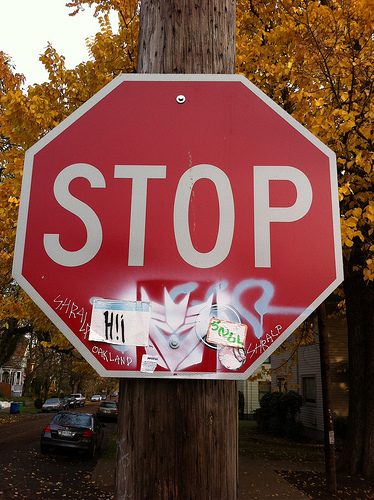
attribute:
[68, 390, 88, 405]
truck — white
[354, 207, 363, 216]
leaves — golden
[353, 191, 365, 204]
leaves — golden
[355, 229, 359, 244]
leaves — golden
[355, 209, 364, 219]
leaves — golden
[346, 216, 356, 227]
leaves — golden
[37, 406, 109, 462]
car — parked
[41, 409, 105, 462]
black car — small, parked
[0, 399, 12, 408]
fence — white, picket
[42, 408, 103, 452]
black car — small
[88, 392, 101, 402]
car — parked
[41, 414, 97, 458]
car — parked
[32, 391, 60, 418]
car — parked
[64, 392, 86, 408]
car — parked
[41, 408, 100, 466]
car — parked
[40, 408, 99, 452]
car — small, black, parked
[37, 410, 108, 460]
black car — small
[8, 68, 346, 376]
sign — graffitied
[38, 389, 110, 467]
car — parked, small, black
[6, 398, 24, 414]
container — blue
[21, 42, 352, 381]
stop sign — red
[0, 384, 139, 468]
cars — parked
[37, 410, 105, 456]
black car — small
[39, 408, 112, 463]
car — small, black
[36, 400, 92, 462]
car — black, small, parked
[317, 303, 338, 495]
pole — wooden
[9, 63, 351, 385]
stop sign — octagon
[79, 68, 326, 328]
sign — red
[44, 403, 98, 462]
car — small, black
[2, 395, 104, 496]
street —  residential